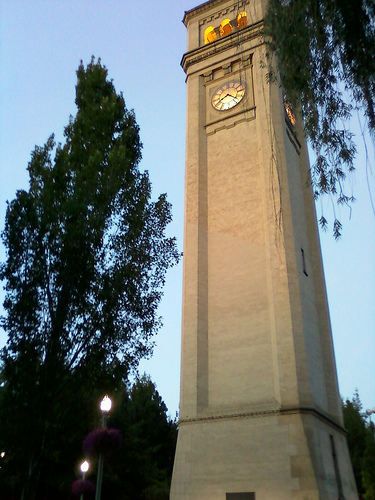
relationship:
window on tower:
[200, 11, 255, 42] [168, 1, 358, 498]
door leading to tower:
[329, 433, 345, 498] [168, 1, 358, 498]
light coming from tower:
[195, 10, 245, 46] [178, 0, 341, 488]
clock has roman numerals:
[210, 81, 250, 109] [233, 87, 242, 103]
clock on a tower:
[210, 81, 247, 113] [177, 4, 324, 408]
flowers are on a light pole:
[86, 425, 123, 456] [93, 392, 115, 428]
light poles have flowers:
[72, 393, 116, 483] [83, 428, 123, 452]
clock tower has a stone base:
[177, 6, 292, 185] [168, 416, 322, 498]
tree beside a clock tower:
[7, 52, 169, 398] [187, 11, 332, 435]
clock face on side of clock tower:
[282, 98, 297, 136] [169, 0, 359, 500]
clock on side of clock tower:
[210, 81, 247, 113] [169, 0, 359, 500]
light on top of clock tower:
[206, 23, 214, 37] [169, 0, 359, 500]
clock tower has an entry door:
[169, 0, 359, 500] [326, 434, 351, 498]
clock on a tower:
[210, 81, 247, 113] [185, 4, 354, 497]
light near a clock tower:
[92, 387, 117, 428] [169, 0, 359, 500]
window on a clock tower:
[296, 247, 312, 277] [169, 0, 359, 500]